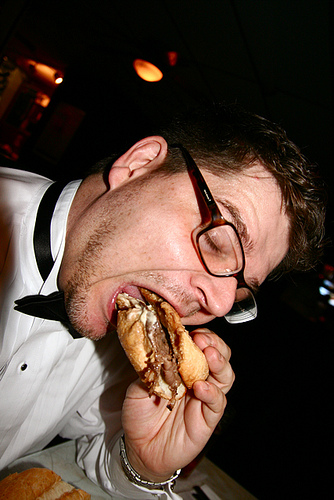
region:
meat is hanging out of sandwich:
[148, 358, 179, 410]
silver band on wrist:
[119, 465, 179, 492]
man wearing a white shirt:
[5, 328, 92, 436]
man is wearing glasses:
[202, 178, 259, 322]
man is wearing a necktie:
[21, 182, 65, 336]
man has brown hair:
[275, 131, 316, 258]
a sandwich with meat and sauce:
[120, 299, 210, 396]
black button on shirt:
[21, 360, 30, 379]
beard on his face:
[64, 228, 97, 337]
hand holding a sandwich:
[162, 332, 251, 482]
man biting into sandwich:
[55, 124, 316, 417]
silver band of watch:
[113, 440, 180, 491]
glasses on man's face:
[188, 199, 268, 329]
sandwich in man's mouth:
[116, 285, 176, 341]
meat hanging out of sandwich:
[144, 341, 186, 403]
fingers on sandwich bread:
[189, 330, 228, 369]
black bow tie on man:
[13, 279, 95, 347]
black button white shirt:
[15, 353, 34, 379]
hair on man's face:
[80, 224, 111, 275]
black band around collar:
[25, 180, 76, 246]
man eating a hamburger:
[65, 122, 325, 418]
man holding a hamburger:
[113, 289, 232, 462]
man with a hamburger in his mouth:
[94, 275, 219, 398]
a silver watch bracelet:
[111, 432, 185, 488]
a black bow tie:
[12, 293, 80, 343]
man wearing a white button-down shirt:
[1, 180, 123, 452]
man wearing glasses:
[175, 132, 266, 322]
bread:
[1, 462, 83, 497]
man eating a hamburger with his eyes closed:
[99, 171, 278, 411]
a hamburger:
[121, 297, 204, 398]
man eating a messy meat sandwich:
[0, 6, 332, 489]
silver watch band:
[118, 446, 146, 485]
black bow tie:
[22, 268, 87, 348]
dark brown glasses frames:
[173, 160, 245, 276]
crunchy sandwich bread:
[4, 469, 83, 498]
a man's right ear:
[101, 135, 173, 182]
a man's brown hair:
[202, 124, 333, 177]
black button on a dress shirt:
[10, 355, 33, 375]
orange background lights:
[11, 47, 182, 115]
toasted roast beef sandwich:
[117, 304, 203, 400]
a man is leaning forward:
[3, 122, 310, 496]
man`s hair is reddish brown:
[242, 98, 330, 288]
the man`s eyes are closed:
[197, 209, 250, 304]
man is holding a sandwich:
[120, 296, 227, 441]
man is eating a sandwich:
[97, 262, 191, 374]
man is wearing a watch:
[85, 418, 178, 489]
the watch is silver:
[96, 430, 180, 495]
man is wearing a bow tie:
[13, 165, 91, 349]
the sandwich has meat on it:
[109, 289, 191, 399]